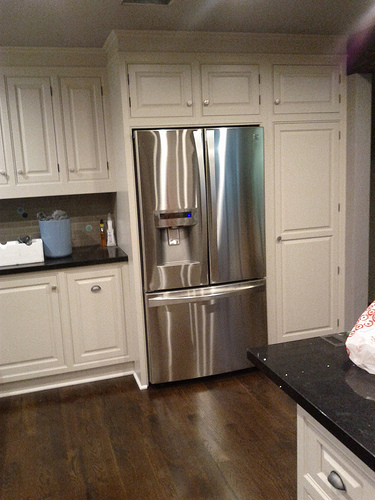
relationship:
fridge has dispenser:
[127, 121, 278, 390] [155, 210, 196, 269]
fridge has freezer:
[127, 121, 278, 390] [136, 279, 274, 386]